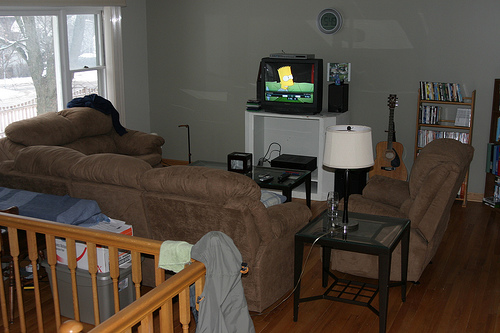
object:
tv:
[255, 57, 321, 114]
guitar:
[368, 93, 408, 184]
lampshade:
[321, 125, 375, 173]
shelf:
[416, 78, 471, 208]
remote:
[257, 172, 273, 182]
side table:
[185, 159, 315, 212]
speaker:
[327, 83, 349, 114]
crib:
[0, 208, 230, 333]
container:
[41, 238, 141, 324]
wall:
[127, 0, 498, 188]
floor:
[227, 197, 497, 333]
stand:
[292, 208, 411, 333]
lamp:
[319, 124, 376, 236]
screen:
[0, 11, 111, 142]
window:
[0, 4, 114, 140]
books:
[421, 80, 424, 100]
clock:
[317, 4, 342, 34]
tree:
[0, 12, 60, 116]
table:
[183, 158, 312, 211]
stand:
[243, 112, 338, 194]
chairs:
[0, 145, 313, 315]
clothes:
[67, 94, 128, 136]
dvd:
[227, 152, 253, 179]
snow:
[0, 74, 110, 141]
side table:
[292, 207, 413, 333]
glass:
[299, 209, 410, 249]